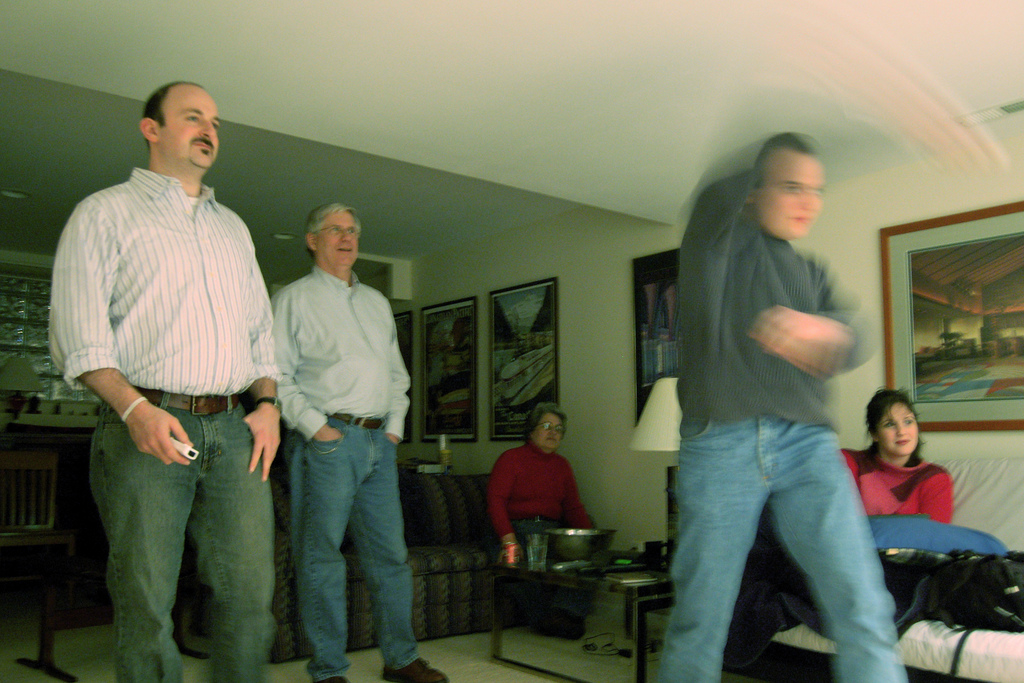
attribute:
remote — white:
[168, 433, 199, 460]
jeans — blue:
[300, 413, 424, 669]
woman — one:
[843, 383, 965, 526]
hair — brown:
[856, 376, 911, 444]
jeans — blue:
[282, 407, 427, 678]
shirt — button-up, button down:
[44, 160, 282, 400]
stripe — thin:
[100, 188, 152, 383]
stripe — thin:
[171, 178, 215, 390]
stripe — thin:
[93, 348, 104, 368]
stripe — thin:
[67, 221, 80, 356]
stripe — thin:
[201, 208, 230, 397]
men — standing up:
[27, 67, 924, 681]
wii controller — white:
[172, 432, 203, 467]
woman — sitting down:
[477, 395, 594, 571]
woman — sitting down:
[842, 367, 961, 515]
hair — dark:
[865, 380, 917, 413]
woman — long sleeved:
[846, 378, 970, 521]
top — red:
[846, 447, 961, 512]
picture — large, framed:
[868, 193, 1022, 436]